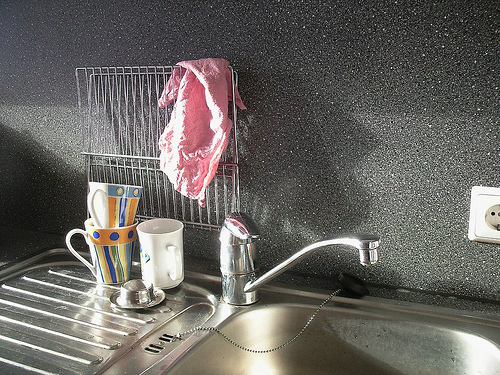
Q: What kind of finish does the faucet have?
A: Chrome.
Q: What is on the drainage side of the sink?
A: Three cups.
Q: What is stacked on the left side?
A: Two mugs.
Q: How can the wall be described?
A: Grey speckled wall.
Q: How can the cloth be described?
A: A pink cloth.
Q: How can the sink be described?
A: A stainless steel sink.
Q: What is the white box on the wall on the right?
A: An outlet.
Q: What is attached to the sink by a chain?
A: A stopper.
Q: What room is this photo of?
A: Kitchen.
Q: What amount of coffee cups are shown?
A: 3.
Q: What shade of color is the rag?
A: Pink.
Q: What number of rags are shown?
A: 1.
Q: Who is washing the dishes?
A: Noone is in the photo.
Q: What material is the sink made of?
A: Metal.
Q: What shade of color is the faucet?
A: Silver.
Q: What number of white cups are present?
A: 1.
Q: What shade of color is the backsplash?
A: Grayish.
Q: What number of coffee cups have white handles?
A: 2.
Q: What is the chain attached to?
A: The stopper.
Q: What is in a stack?
A: Mugs.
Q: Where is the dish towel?
A: On a rack.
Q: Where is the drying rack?
A: Against the wall.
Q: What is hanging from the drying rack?
A: A towel.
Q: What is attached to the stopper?
A: A chain.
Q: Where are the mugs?
A: On the sink.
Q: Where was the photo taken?
A: A kitchen.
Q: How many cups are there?
A: Three.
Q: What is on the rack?
A: A rag.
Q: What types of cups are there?
A: Coffee cups.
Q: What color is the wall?
A: Black.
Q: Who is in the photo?
A: No one.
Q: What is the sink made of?
A: Metal.